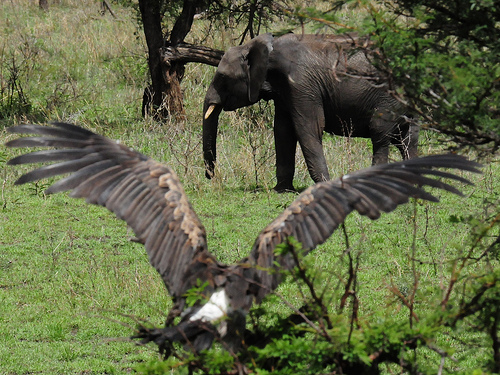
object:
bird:
[8, 121, 485, 358]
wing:
[250, 152, 485, 293]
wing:
[5, 119, 206, 305]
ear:
[246, 37, 273, 103]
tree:
[129, 0, 200, 125]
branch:
[158, 41, 226, 70]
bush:
[164, 138, 191, 169]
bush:
[246, 130, 264, 188]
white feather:
[189, 291, 228, 326]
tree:
[145, 175, 500, 374]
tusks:
[200, 101, 218, 120]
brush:
[277, 228, 337, 332]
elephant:
[196, 24, 430, 195]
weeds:
[139, 134, 151, 159]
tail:
[126, 318, 200, 359]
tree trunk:
[133, 2, 171, 52]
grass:
[25, 167, 50, 199]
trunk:
[201, 86, 226, 181]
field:
[0, 0, 500, 374]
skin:
[311, 67, 341, 102]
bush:
[373, 104, 496, 148]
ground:
[0, 1, 500, 374]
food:
[129, 132, 166, 164]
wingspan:
[1, 120, 486, 306]